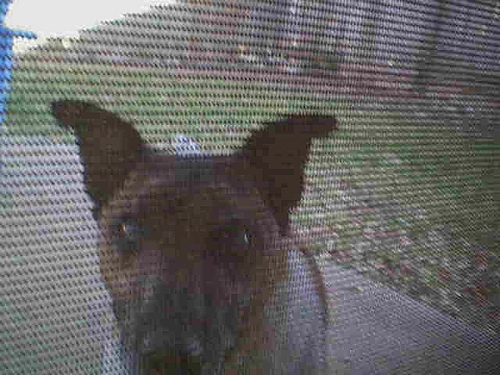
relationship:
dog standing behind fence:
[48, 89, 342, 374] [4, 1, 498, 96]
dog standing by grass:
[48, 89, 342, 374] [362, 128, 497, 225]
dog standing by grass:
[48, 89, 342, 374] [343, 175, 430, 262]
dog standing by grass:
[48, 89, 342, 374] [16, 71, 41, 111]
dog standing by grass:
[48, 89, 342, 374] [77, 78, 283, 101]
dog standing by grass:
[48, 89, 342, 374] [165, 100, 223, 132]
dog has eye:
[48, 97, 338, 373] [118, 215, 145, 243]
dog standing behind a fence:
[48, 89, 342, 374] [0, 2, 497, 374]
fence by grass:
[0, 2, 497, 374] [134, 67, 234, 131]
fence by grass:
[0, 2, 497, 374] [323, 100, 494, 315]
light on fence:
[7, 0, 162, 58] [18, 0, 498, 127]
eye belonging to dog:
[223, 223, 254, 259] [48, 89, 342, 374]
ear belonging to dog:
[230, 111, 350, 231] [48, 89, 342, 374]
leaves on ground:
[381, 139, 493, 221] [348, 103, 498, 304]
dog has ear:
[48, 89, 342, 374] [43, 94, 146, 207]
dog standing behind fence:
[48, 89, 342, 374] [0, 2, 497, 374]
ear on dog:
[43, 99, 151, 215] [48, 89, 342, 374]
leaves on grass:
[346, 185, 446, 233] [5, 63, 497, 332]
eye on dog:
[223, 223, 254, 259] [48, 89, 342, 374]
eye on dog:
[118, 215, 145, 243] [48, 89, 342, 374]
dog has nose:
[48, 89, 342, 374] [133, 327, 199, 370]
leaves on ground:
[319, 187, 477, 297] [42, 52, 497, 343]